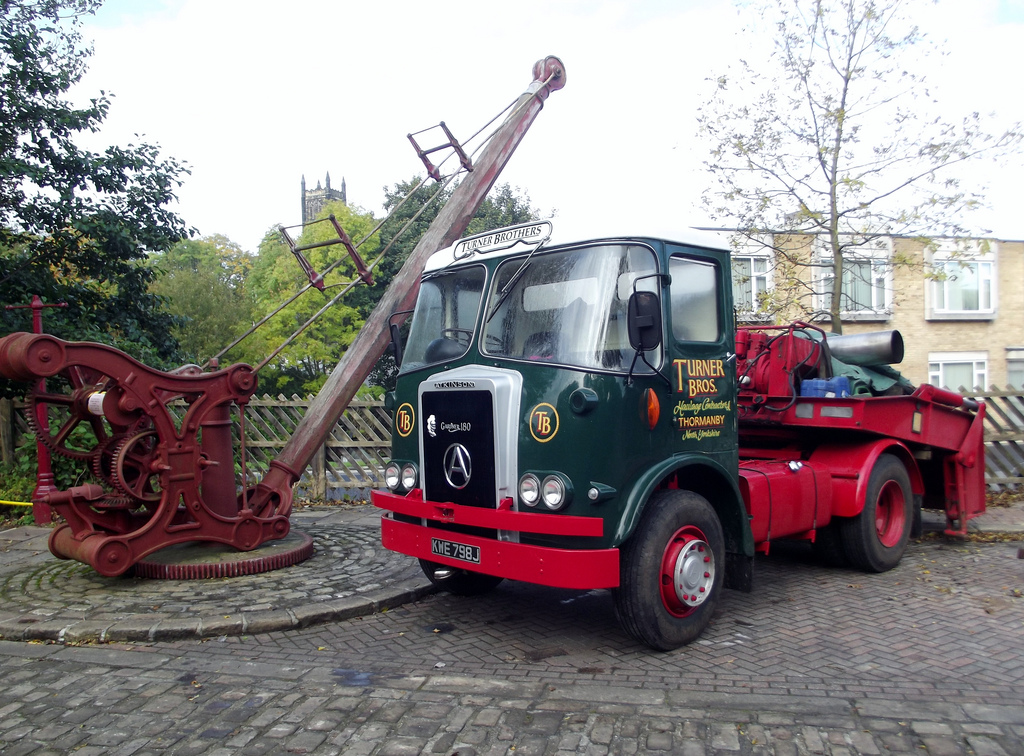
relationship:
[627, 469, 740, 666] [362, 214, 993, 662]
tire on truck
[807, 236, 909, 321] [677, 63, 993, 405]
window on top of building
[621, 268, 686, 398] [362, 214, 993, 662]
side mirror attached to truck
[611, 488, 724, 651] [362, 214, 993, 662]
tire attached to truck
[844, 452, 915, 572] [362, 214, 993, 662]
tire attached to truck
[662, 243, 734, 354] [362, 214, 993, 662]
window attached to truck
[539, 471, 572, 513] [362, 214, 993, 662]
light attached to truck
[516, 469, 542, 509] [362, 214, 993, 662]
light attached to truck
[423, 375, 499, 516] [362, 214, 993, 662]
grill on truck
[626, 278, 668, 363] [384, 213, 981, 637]
mirror on truck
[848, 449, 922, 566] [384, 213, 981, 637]
tire on truck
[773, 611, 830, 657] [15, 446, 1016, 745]
brick on ground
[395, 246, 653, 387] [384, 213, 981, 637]
windshield on truck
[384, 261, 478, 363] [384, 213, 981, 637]
windshield on truck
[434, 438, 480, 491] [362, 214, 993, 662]
logo on truck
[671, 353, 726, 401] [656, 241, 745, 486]
print on door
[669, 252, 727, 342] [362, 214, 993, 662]
window on truck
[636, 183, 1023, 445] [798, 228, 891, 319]
building with window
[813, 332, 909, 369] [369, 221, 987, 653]
pipe on truck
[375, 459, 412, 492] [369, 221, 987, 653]
headlight on truck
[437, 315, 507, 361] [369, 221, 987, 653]
steering wheel inside truck